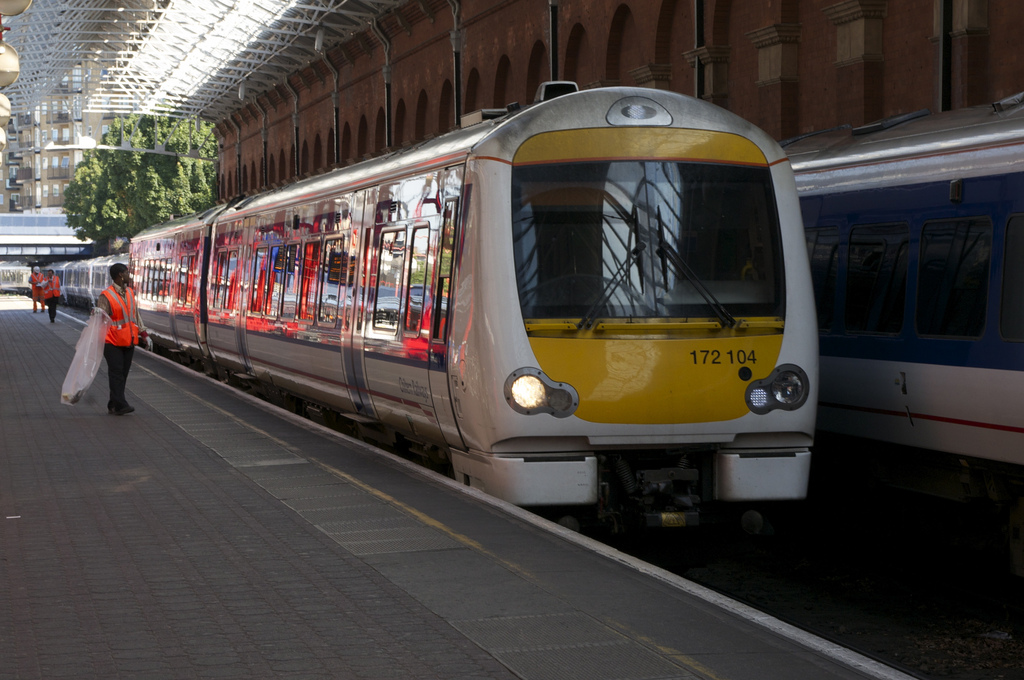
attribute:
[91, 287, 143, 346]
vest — bright orange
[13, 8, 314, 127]
ceiling — scaffolding, skylight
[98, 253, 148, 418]
worker — plastic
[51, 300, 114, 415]
bag — large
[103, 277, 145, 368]
vest — orange 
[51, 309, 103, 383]
bag — plastic 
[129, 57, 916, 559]
train — headlight  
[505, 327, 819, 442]
train — headlight  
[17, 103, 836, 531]
train — white, yellow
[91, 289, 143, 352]
vest — orange